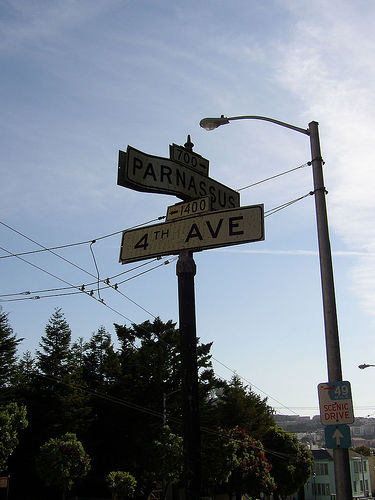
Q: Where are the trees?
A: Behind the street sign.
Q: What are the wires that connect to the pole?
A: Electrical.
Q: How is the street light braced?
A: On metal pole.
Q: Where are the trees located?
A: Left of street.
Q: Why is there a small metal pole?
A: For street signs.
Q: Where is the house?
A: Bottom right.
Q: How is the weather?
A: Partly cloudy.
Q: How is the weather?
A: Fair.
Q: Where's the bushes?
A: Under signs.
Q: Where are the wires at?
A: Overhead.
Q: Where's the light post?
A: Right.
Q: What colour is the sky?
A: Blue.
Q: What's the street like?
A: Hill.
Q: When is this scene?
A: Late afternoon.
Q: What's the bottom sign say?
A: 4th Ave.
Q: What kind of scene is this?
A: Street corner.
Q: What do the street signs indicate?
A: 4rth and Parnassus ave.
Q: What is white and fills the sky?
A: Clouds.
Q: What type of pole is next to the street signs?
A: Light.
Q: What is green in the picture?
A: A tree.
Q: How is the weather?
A: Sunny.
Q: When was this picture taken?
A: Afternoon.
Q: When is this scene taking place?
A: Daytime.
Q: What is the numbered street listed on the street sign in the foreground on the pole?
A: 4th avenue.